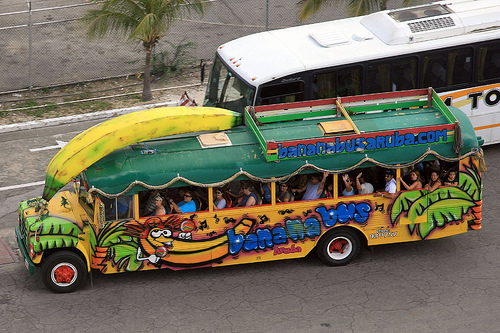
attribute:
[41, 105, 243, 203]
banana — large, yellow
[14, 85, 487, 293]
bus — large, white, yellow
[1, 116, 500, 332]
road — cracked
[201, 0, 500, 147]
bus — white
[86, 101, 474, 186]
roof — green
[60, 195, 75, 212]
lizard — plastic, small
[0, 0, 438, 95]
fence — mesh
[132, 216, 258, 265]
banana — painted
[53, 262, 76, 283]
hubcap — red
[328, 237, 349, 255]
hubcap — red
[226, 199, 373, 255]
letters — blue